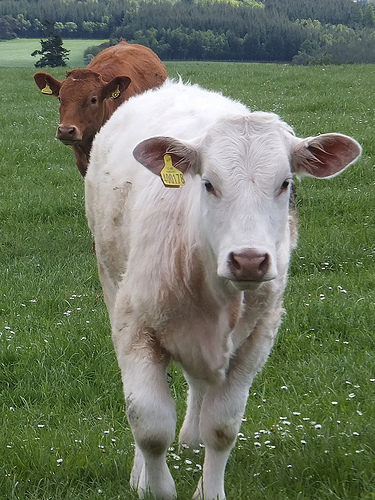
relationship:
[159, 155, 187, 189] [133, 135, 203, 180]
tag in ear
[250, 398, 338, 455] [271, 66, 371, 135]
flowers in grass.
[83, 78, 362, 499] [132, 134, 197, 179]
cow has ear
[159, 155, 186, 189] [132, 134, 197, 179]
tag in ear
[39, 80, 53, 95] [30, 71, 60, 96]
tag in ear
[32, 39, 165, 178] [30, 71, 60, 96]
cow has ear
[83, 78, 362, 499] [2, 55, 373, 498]
cow standing in pasture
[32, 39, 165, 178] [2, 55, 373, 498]
cow standing in pasture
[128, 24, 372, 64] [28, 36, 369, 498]
bushes behind cows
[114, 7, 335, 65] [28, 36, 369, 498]
trees behind cows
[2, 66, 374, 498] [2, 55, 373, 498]
plants on pasture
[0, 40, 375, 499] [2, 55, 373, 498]
pasture on pasture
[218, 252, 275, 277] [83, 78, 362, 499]
nose on cow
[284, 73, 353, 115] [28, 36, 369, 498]
pasture for cows